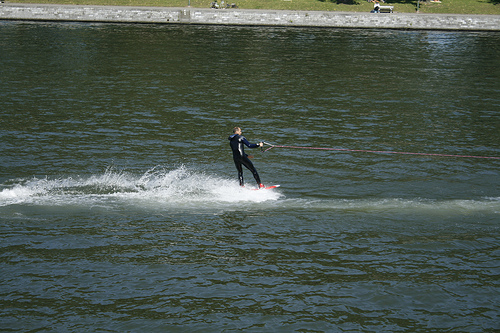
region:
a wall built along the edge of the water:
[0, 3, 498, 32]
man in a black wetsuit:
[220, 124, 268, 181]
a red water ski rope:
[257, 133, 499, 170]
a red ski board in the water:
[253, 168, 285, 198]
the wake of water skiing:
[0, 149, 227, 210]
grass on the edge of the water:
[195, 1, 497, 18]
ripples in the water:
[0, 22, 499, 152]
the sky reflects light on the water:
[2, 220, 479, 331]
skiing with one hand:
[219, 111, 289, 193]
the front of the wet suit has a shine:
[231, 130, 251, 161]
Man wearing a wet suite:
[222, 115, 299, 207]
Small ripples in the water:
[12, 274, 78, 329]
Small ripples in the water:
[80, 272, 137, 324]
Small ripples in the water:
[137, 269, 229, 330]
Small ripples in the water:
[222, 266, 290, 322]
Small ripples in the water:
[287, 266, 349, 325]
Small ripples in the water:
[342, 269, 380, 306]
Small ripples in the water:
[381, 265, 437, 323]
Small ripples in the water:
[424, 267, 486, 329]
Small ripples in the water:
[355, 99, 418, 153]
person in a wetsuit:
[219, 125, 272, 215]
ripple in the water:
[279, 251, 319, 283]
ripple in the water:
[383, 293, 419, 318]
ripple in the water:
[101, 273, 123, 294]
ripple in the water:
[368, 198, 387, 213]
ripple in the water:
[314, 295, 346, 317]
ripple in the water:
[362, 155, 397, 177]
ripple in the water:
[103, 186, 127, 201]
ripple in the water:
[124, 143, 149, 163]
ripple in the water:
[311, 138, 341, 159]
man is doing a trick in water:
[216, 120, 256, 185]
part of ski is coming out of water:
[265, 180, 282, 186]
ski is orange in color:
[260, 185, 282, 191]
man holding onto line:
[261, 138, 497, 178]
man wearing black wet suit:
[227, 127, 252, 188]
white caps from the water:
[12, 172, 268, 203]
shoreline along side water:
[2, 2, 484, 22]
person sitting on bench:
[347, 1, 403, 17]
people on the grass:
[202, 0, 240, 10]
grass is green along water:
[423, 1, 493, 12]